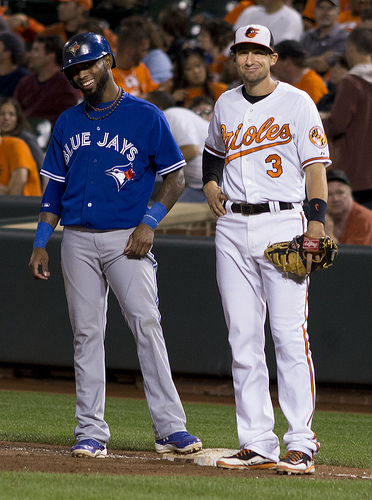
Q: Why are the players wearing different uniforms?
A: They are on different baseball teams.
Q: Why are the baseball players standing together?
A: They are in a game.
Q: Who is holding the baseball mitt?
A: The player with the Orioles uniform.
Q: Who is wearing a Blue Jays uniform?
A: The player on the left.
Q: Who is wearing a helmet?
A: The man in the Blue Jays uniform.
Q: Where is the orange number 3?
A: On the Orioles shirt.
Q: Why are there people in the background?
A: They are watching the baseball game.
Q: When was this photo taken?
A: During a baseball game.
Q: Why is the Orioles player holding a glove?
A: To catch the baseball.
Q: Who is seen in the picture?
A: Players.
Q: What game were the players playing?
A: Baseball.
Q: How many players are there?
A: Two.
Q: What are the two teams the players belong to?
A: Blue Jays and Orioles.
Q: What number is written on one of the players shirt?
A: Three.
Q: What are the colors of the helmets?
A: Blue and white.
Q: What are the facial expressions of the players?
A: Both are smiling.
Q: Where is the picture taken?
A: On the baseball ground.